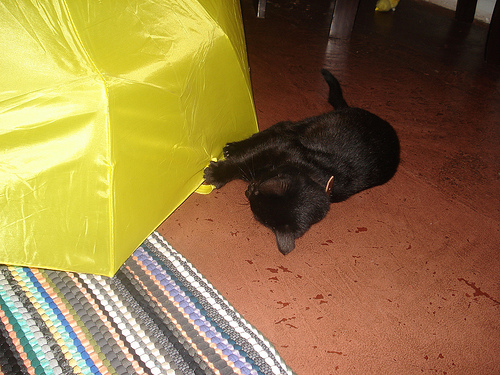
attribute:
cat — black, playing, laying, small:
[245, 73, 424, 230]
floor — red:
[270, 41, 489, 322]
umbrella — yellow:
[2, 7, 242, 233]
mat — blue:
[7, 227, 202, 366]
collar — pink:
[308, 163, 338, 198]